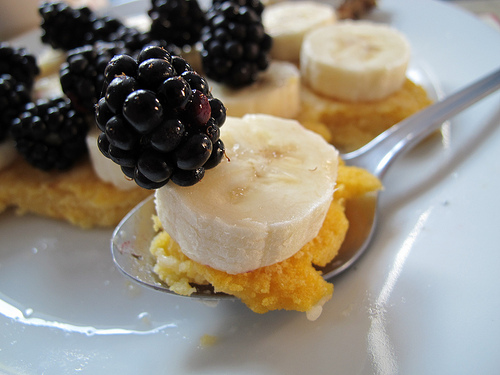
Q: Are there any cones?
A: No, there are no cones.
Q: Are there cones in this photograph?
A: No, there are no cones.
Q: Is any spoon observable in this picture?
A: Yes, there is a spoon.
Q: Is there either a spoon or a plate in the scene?
A: Yes, there is a spoon.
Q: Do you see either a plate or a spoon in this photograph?
A: Yes, there is a spoon.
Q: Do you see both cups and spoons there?
A: No, there is a spoon but no cups.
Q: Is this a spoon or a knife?
A: This is a spoon.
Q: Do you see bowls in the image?
A: No, there are no bowls.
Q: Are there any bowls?
A: No, there are no bowls.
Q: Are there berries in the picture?
A: Yes, there are berries.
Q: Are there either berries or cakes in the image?
A: Yes, there are berries.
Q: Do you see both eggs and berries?
A: No, there are berries but no eggs.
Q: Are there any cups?
A: No, there are no cups.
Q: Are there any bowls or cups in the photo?
A: No, there are no cups or bowls.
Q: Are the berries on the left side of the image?
A: Yes, the berries are on the left of the image.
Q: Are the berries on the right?
A: No, the berries are on the left of the image.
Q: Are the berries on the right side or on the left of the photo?
A: The berries are on the left of the image.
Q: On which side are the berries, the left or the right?
A: The berries are on the left of the image.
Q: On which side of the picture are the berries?
A: The berries are on the left of the image.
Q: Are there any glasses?
A: No, there are no glasses.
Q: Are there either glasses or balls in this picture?
A: No, there are no glasses or balls.